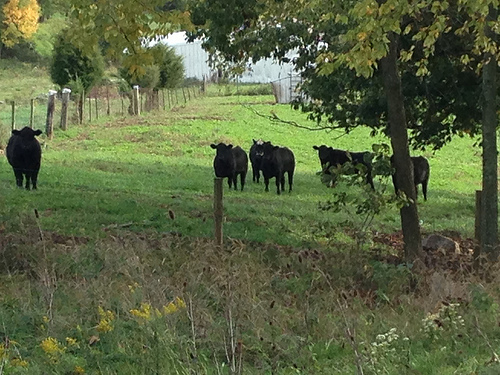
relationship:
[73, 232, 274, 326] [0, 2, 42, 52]
leaves on a tree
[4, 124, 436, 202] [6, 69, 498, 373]
cows standing in a field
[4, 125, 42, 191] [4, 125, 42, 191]
cow black cow standing cow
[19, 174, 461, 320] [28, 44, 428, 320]
shaded area in field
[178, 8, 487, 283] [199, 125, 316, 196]
two trees shading cows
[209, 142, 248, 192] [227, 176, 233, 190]
cow four leg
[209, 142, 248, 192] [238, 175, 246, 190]
cow four leg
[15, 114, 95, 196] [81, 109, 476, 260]
cow standing in field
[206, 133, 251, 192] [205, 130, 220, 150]
cow has ear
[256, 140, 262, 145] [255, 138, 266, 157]
spot on head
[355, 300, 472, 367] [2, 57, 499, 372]
flowers are on grass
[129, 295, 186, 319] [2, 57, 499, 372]
flowers are on grass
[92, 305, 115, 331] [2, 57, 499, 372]
flowers are on grass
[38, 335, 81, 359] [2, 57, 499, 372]
flowers are on grass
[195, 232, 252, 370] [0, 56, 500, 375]
plants are on field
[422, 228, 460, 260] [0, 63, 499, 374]
rock on ground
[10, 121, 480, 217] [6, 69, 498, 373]
cows are in field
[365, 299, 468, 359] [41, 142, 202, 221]
flowers are in grass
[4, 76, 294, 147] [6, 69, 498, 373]
fence at edge of field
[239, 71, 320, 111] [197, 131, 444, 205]
fence behind cows